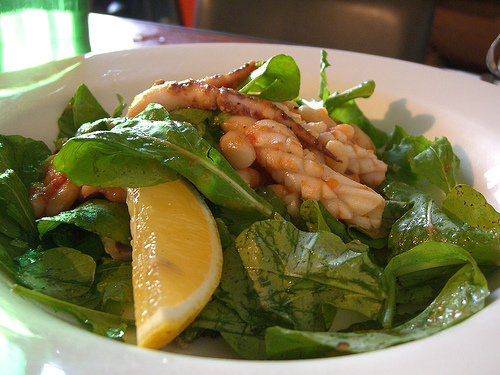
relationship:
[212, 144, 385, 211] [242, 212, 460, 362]
cooked meat on salad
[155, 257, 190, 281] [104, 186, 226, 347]
seed in lemon